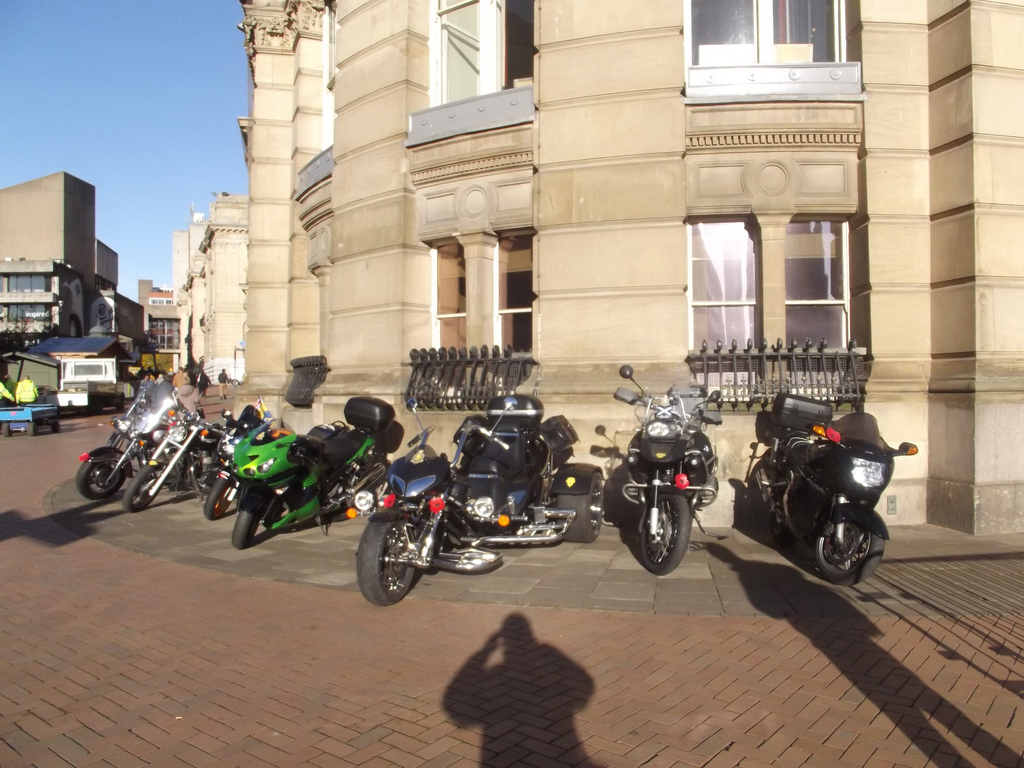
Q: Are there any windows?
A: Yes, there is a window.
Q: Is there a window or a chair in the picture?
A: Yes, there is a window.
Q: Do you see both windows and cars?
A: No, there is a window but no cars.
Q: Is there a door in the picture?
A: No, there are no doors.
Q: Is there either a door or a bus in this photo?
A: No, there are no doors or buses.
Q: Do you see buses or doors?
A: No, there are no doors or buses.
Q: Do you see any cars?
A: No, there are no cars.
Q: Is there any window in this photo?
A: Yes, there is a window.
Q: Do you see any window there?
A: Yes, there is a window.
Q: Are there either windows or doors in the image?
A: Yes, there is a window.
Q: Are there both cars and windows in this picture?
A: No, there is a window but no cars.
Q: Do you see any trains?
A: No, there are no trains.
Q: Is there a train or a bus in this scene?
A: No, there are no trains or buses.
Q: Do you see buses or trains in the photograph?
A: No, there are no trains or buses.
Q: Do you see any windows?
A: Yes, there is a window.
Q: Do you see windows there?
A: Yes, there is a window.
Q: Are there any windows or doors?
A: Yes, there is a window.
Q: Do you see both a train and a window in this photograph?
A: No, there is a window but no trains.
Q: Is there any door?
A: No, there are no doors.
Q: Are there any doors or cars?
A: No, there are no doors or cars.